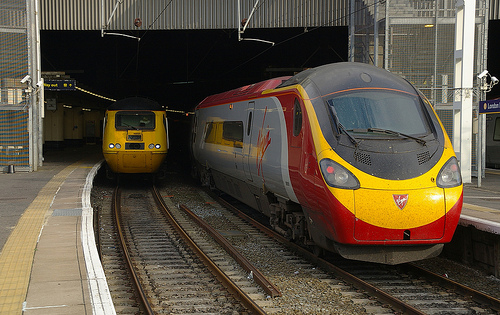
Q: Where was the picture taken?
A: Train station.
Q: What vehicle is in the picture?
A: Trains.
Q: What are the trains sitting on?
A: Tracks.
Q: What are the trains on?
A: Brown tracks.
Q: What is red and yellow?
A: The train.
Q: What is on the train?
A: Windows.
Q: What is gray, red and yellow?
A: The train.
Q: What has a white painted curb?
A: The stone paving.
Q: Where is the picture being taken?
A: A train yard.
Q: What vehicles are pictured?
A: Trains.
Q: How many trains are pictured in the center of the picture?
A: 2.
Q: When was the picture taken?
A: Daytime.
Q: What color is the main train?
A: Grey, red and yellow.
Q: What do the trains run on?
A: The rails.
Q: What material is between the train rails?
A: Gravel.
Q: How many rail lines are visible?
A: 2.